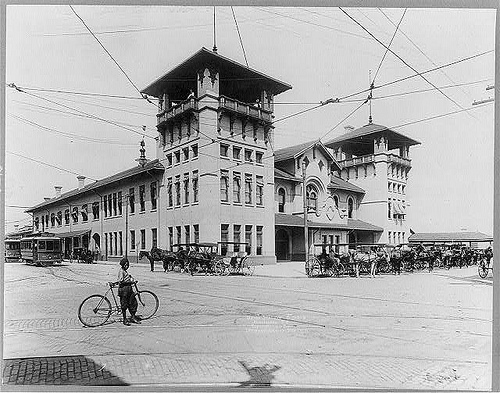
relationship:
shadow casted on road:
[2, 355, 129, 385] [3, 256, 484, 388]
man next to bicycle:
[117, 256, 142, 327] [78, 278, 160, 327]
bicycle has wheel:
[78, 278, 160, 327] [77, 293, 116, 329]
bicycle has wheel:
[78, 278, 160, 327] [127, 287, 160, 320]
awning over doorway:
[274, 208, 381, 233] [278, 231, 308, 261]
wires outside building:
[41, 38, 159, 165] [128, 60, 343, 230]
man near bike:
[117, 256, 142, 327] [79, 268, 137, 320]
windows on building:
[130, 190, 231, 219] [110, 159, 287, 239]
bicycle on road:
[78, 279, 160, 327] [162, 302, 233, 324]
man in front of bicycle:
[114, 251, 158, 320] [77, 289, 137, 326]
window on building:
[208, 163, 248, 203] [199, 124, 319, 278]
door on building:
[270, 221, 301, 258] [195, 162, 280, 271]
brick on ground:
[17, 360, 39, 373] [36, 321, 100, 351]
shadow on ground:
[51, 336, 185, 384] [223, 344, 292, 386]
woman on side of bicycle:
[122, 252, 134, 309] [76, 285, 138, 332]